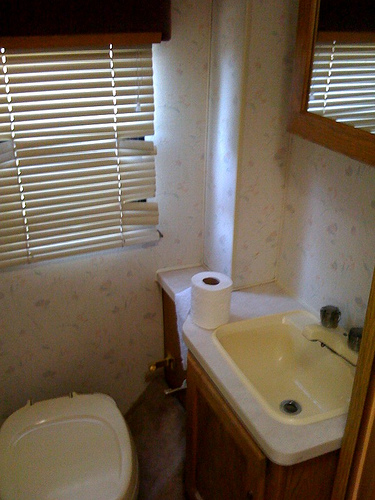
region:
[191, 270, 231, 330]
A roll of toilet paper.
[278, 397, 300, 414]
The sink drain.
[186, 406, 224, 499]
Part of the brown cupboard.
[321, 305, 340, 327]
A grey sink handle.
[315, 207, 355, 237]
Part of the wall.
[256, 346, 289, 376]
Part of the sink.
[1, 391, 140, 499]
A white toilet.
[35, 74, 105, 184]
Part of the blinds.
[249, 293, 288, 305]
Part of the counter.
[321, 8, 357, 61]
Part of the mirror.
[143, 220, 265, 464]
This is a bathroom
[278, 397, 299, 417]
This is a drain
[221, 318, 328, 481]
This is a sink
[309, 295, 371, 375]
This is a faucet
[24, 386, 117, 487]
This is a toilet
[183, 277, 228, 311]
This is a toilet paper roll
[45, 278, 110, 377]
This is pink wallpaper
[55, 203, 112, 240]
These are blinds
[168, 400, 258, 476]
This is a wooden sink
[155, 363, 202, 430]
This is a metal bar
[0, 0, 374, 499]
old small bathroom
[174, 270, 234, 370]
toilet paper roll on counter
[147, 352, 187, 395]
toilet paper holder is broken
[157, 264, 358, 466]
counter is linoleum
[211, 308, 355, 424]
white sink in counter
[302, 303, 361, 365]
white faucet over sink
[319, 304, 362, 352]
grey handles around faucet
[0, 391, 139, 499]
white toilet next to toilet paper holder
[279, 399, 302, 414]
silver metal drain in sink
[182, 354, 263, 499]
wooden door under sink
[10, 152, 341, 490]
a rest room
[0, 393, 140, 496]
a white toilet lid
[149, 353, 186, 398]
a toilet paper holder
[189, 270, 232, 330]
a roll of toilet paper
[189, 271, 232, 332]
a white toilet paper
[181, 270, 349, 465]
a toilet paper on the counter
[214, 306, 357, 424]
a sink and faucet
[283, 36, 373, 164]
part of a mirror on the wall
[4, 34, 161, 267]
window blinds hanging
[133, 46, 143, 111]
string of the window blinds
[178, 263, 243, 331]
toilet paper on sink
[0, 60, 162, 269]
blinds on a window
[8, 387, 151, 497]
toilet bowl in bathroom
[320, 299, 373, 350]
water knobs on sink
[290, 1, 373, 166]
mirror mounted on wall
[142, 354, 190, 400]
toilet paper holder on wall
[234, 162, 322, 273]
patterned wallpaper on bathroom wall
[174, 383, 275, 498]
wooden cabinet under sink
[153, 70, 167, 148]
sunlight shining through the window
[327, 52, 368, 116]
reflection in the mirror